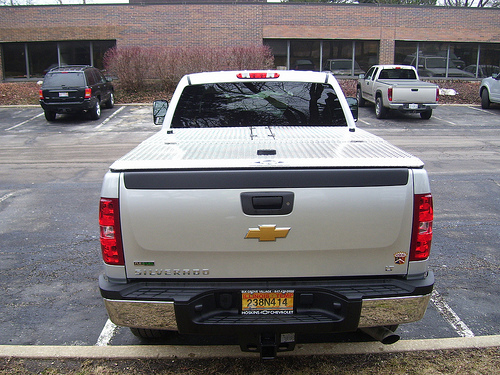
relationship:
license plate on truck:
[241, 287, 295, 314] [97, 71, 436, 365]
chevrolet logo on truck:
[244, 223, 291, 244] [97, 71, 436, 365]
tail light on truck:
[99, 197, 125, 265] [97, 71, 436, 365]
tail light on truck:
[408, 192, 433, 262] [97, 71, 436, 365]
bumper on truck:
[97, 275, 434, 329] [97, 71, 436, 365]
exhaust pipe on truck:
[360, 325, 400, 346] [97, 71, 436, 365]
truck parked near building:
[354, 63, 441, 121] [2, 2, 500, 83]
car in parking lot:
[38, 63, 115, 122] [0, 102, 499, 355]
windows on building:
[0, 39, 118, 81] [2, 2, 500, 83]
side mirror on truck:
[152, 99, 169, 125] [97, 71, 436, 365]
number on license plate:
[247, 298, 289, 308] [241, 287, 295, 314]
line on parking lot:
[94, 315, 119, 347] [0, 102, 499, 355]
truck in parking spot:
[354, 63, 441, 121] [355, 103, 453, 127]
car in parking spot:
[38, 63, 115, 122] [5, 104, 126, 137]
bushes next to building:
[102, 46, 274, 93] [2, 2, 500, 83]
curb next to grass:
[0, 336, 498, 357] [2, 351, 499, 374]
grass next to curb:
[2, 351, 499, 374] [0, 336, 498, 357]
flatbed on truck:
[98, 129, 436, 282] [97, 71, 436, 365]